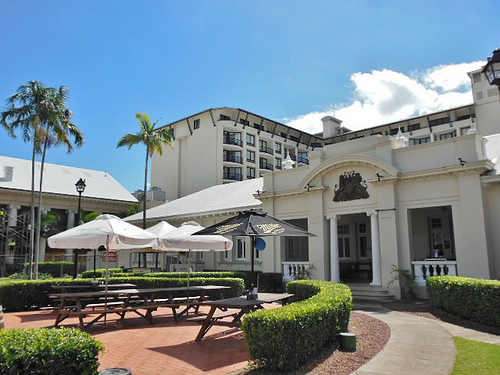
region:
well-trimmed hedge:
[251, 312, 302, 363]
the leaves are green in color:
[270, 315, 320, 350]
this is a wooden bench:
[60, 306, 179, 328]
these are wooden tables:
[52, 283, 228, 302]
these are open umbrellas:
[60, 223, 250, 245]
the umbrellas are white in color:
[99, 226, 179, 243]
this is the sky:
[72, 15, 210, 73]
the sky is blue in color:
[23, 10, 269, 61]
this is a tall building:
[315, 122, 406, 280]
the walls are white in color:
[455, 174, 496, 261]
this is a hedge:
[244, 322, 292, 359]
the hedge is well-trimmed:
[268, 308, 320, 353]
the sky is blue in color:
[94, 25, 231, 75]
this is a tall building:
[353, 126, 398, 291]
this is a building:
[139, 87, 498, 270]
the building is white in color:
[319, 118, 462, 267]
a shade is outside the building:
[56, 212, 284, 307]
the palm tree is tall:
[10, 85, 68, 166]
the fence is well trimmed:
[267, 307, 341, 352]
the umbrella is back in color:
[226, 214, 271, 233]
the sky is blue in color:
[0, 1, 409, 64]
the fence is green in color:
[247, 308, 324, 364]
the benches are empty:
[80, 283, 207, 324]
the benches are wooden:
[75, 287, 195, 313]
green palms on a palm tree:
[4, 75, 77, 297]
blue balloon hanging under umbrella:
[246, 224, 277, 266]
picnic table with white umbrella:
[44, 208, 153, 328]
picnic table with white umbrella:
[141, 216, 218, 321]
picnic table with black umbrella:
[203, 205, 301, 360]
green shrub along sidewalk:
[232, 271, 369, 373]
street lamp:
[69, 171, 91, 301]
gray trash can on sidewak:
[334, 325, 368, 370]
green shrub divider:
[5, 273, 127, 325]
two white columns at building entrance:
[316, 197, 407, 325]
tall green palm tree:
[14, 67, 74, 289]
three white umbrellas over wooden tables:
[47, 212, 234, 261]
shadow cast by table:
[180, 328, 239, 368]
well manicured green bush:
[251, 265, 358, 367]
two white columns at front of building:
[326, 197, 384, 288]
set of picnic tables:
[31, 203, 303, 336]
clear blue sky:
[109, 30, 335, 91]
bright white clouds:
[356, 50, 472, 125]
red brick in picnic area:
[115, 327, 172, 361]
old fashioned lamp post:
[70, 165, 95, 230]